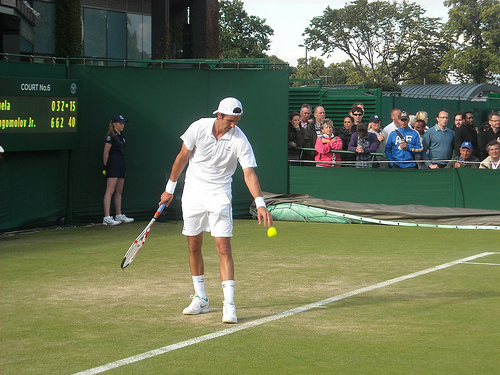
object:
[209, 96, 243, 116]
hat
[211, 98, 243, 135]
head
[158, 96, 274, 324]
tennis player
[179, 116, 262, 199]
shirt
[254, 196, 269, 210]
band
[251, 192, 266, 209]
wrist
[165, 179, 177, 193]
band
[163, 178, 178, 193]
wrist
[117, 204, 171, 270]
tennis racket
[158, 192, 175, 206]
hand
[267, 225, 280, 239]
tennis ball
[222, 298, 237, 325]
shoes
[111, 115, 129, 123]
hat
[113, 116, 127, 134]
head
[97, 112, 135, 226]
woman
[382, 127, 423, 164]
jacket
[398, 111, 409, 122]
hat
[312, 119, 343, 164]
lady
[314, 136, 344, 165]
coat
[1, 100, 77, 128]
text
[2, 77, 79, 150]
display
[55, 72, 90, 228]
corner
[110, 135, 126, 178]
black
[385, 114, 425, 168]
spectators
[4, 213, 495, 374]
tennis court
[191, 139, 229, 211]
white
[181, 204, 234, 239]
shorts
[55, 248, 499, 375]
markings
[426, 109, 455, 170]
guy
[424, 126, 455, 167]
sweater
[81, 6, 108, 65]
doors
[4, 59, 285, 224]
wall